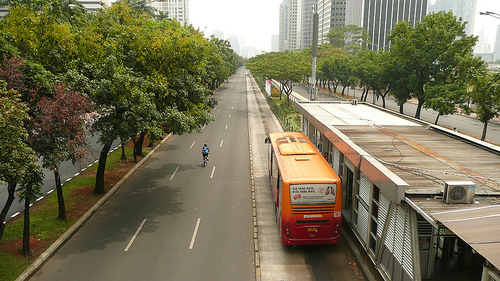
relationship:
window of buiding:
[362, 15, 371, 30] [344, 0, 424, 104]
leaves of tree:
[389, 22, 431, 93] [378, 15, 427, 119]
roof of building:
[313, 98, 493, 220] [261, 0, 388, 45]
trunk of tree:
[20, 243, 34, 257] [52, 160, 69, 222]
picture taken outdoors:
[25, 16, 455, 256] [52, 22, 471, 272]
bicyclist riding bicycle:
[201, 140, 212, 167] [201, 150, 209, 167]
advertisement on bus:
[287, 180, 337, 206] [262, 127, 347, 252]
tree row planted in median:
[1, 0, 242, 256] [1, 127, 173, 279]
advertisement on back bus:
[290, 183, 337, 205] [216, 121, 400, 233]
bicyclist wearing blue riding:
[202, 143, 211, 163] [201, 147, 210, 155]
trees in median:
[232, 8, 487, 103] [246, 33, 497, 164]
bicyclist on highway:
[202, 143, 211, 163] [26, 64, 261, 279]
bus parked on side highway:
[262, 127, 347, 252] [0, 66, 262, 281]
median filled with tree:
[1, 105, 162, 280] [83, 0, 212, 198]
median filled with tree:
[1, 105, 162, 280] [5, 3, 127, 221]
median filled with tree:
[1, 105, 162, 280] [4, 56, 92, 259]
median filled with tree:
[1, 105, 162, 280] [395, 8, 472, 120]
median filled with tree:
[1, 105, 162, 280] [466, 70, 498, 138]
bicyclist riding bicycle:
[202, 143, 211, 163] [200, 140, 210, 166]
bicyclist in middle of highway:
[202, 143, 211, 163] [0, 66, 262, 281]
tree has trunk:
[0, 53, 99, 222] [48, 177, 68, 217]